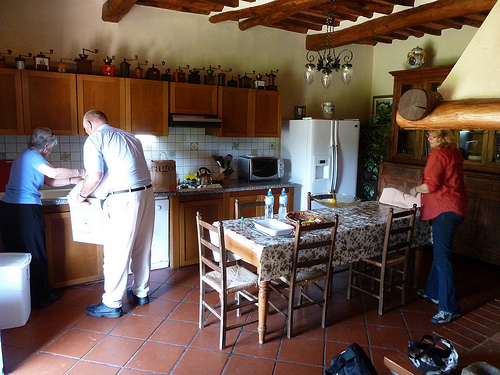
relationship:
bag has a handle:
[151, 151, 179, 193] [158, 151, 168, 159]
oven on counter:
[235, 156, 287, 185] [10, 176, 299, 204]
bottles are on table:
[265, 186, 290, 219] [209, 199, 436, 343]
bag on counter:
[151, 151, 179, 193] [10, 176, 299, 204]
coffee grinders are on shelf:
[0, 46, 281, 93] [1, 67, 280, 93]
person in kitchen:
[70, 111, 155, 318] [1, 1, 499, 374]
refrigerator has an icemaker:
[289, 117, 362, 207] [315, 157, 331, 180]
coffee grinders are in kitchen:
[0, 46, 281, 93] [1, 1, 499, 374]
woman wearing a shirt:
[412, 128, 466, 323] [419, 146, 469, 227]